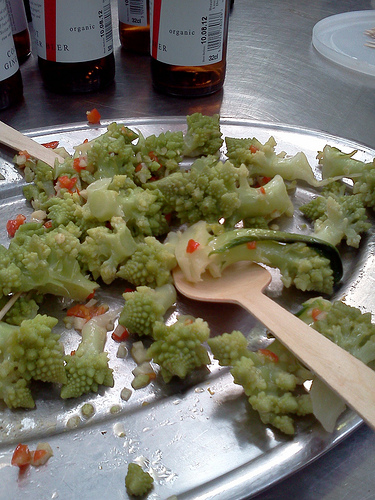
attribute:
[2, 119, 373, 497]
plate — round, silver, green, steamed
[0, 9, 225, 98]
bottle — brown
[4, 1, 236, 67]
label — white, black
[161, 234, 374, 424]
spoon — wooden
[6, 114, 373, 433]
flower — green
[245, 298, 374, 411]
handle — wooden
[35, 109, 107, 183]
tomato — chopped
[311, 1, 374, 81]
lid — white, plastic, round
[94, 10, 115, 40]
barcode — black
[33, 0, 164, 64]
stripes — red